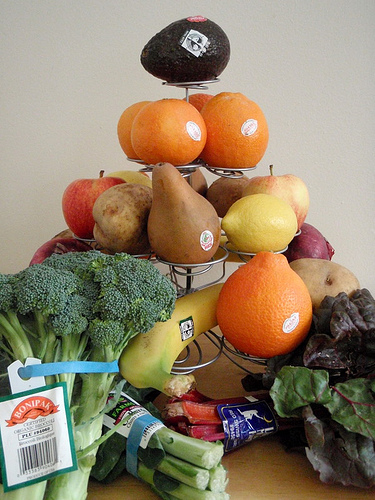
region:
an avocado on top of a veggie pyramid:
[139, 12, 227, 82]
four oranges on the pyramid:
[120, 93, 267, 168]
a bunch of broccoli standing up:
[3, 258, 175, 497]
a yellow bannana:
[119, 284, 226, 394]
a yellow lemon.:
[223, 199, 293, 250]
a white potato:
[294, 260, 358, 302]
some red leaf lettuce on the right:
[272, 295, 374, 485]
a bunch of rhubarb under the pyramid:
[169, 392, 284, 452]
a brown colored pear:
[151, 163, 218, 259]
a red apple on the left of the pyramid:
[64, 177, 121, 235]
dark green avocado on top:
[131, 11, 286, 95]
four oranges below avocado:
[116, 86, 279, 165]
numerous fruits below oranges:
[75, 157, 308, 259]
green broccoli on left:
[15, 246, 188, 491]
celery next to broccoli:
[100, 398, 217, 497]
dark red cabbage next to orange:
[286, 309, 367, 495]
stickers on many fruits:
[142, 29, 258, 160]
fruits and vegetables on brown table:
[39, 34, 350, 496]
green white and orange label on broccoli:
[0, 375, 90, 498]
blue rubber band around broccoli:
[26, 343, 142, 408]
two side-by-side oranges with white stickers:
[133, 92, 269, 166]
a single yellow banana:
[118, 281, 226, 397]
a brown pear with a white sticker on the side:
[149, 162, 221, 261]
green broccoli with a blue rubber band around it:
[1, 248, 175, 495]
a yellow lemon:
[219, 194, 296, 254]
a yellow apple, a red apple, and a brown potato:
[61, 171, 151, 251]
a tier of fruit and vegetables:
[2, 15, 372, 497]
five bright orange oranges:
[116, 91, 312, 359]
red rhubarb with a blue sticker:
[167, 390, 299, 448]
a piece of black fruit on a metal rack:
[140, 16, 228, 93]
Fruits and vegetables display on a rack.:
[10, 5, 365, 490]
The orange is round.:
[129, 97, 205, 163]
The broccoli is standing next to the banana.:
[2, 246, 172, 494]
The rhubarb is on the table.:
[191, 355, 371, 439]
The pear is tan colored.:
[147, 159, 217, 260]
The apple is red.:
[60, 168, 92, 237]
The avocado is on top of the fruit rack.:
[135, 12, 231, 87]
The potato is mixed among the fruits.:
[93, 182, 144, 246]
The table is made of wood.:
[227, 456, 310, 492]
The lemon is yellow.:
[220, 192, 295, 248]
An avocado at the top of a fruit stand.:
[121, 4, 247, 90]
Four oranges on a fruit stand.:
[110, 90, 272, 166]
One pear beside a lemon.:
[141, 161, 225, 264]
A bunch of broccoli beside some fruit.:
[1, 227, 185, 498]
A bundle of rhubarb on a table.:
[163, 377, 289, 450]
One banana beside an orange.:
[109, 272, 229, 397]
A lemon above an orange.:
[216, 179, 315, 367]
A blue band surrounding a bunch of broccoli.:
[2, 353, 126, 380]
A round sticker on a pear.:
[146, 157, 225, 264]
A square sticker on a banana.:
[116, 279, 225, 396]